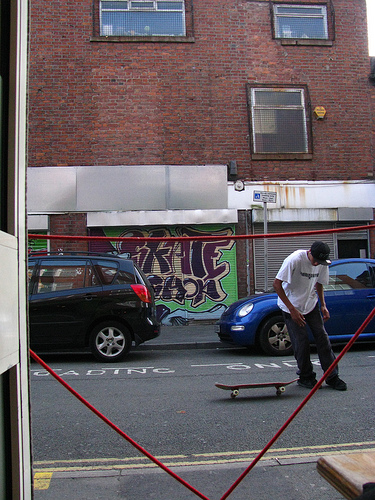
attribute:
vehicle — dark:
[25, 252, 166, 364]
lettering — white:
[33, 356, 331, 374]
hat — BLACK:
[314, 249, 331, 267]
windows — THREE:
[88, 2, 345, 155]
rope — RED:
[133, 231, 355, 256]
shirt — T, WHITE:
[281, 260, 335, 312]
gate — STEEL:
[155, 258, 230, 300]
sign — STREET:
[249, 188, 285, 200]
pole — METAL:
[260, 214, 267, 278]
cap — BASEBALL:
[311, 243, 328, 263]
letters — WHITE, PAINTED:
[106, 360, 165, 384]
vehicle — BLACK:
[34, 261, 153, 355]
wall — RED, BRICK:
[99, 126, 131, 145]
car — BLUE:
[234, 258, 363, 341]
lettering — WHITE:
[84, 359, 168, 382]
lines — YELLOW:
[205, 447, 234, 464]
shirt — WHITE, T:
[284, 261, 329, 313]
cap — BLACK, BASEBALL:
[314, 235, 326, 257]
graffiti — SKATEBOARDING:
[142, 246, 210, 300]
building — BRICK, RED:
[108, 68, 194, 138]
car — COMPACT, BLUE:
[262, 251, 362, 333]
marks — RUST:
[271, 188, 298, 196]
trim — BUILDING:
[273, 180, 363, 217]